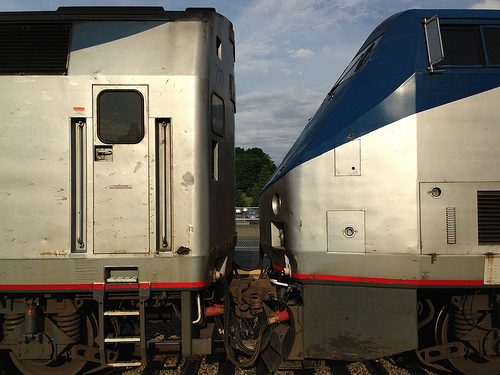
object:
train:
[2, 5, 497, 375]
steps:
[93, 283, 151, 370]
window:
[96, 89, 145, 144]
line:
[0, 282, 206, 291]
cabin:
[258, 8, 497, 288]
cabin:
[0, 5, 239, 294]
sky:
[240, 2, 295, 125]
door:
[92, 82, 156, 255]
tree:
[230, 146, 277, 207]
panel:
[326, 209, 367, 253]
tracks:
[1, 350, 499, 374]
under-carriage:
[2, 295, 499, 367]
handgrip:
[155, 117, 172, 251]